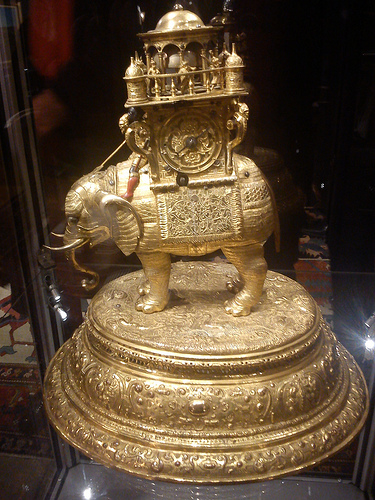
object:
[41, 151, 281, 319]
elephant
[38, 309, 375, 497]
table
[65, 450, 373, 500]
surface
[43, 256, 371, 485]
bottom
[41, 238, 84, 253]
tusk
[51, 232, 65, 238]
tusk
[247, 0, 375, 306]
surface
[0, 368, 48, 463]
mat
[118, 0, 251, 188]
model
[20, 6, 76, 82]
object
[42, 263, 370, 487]
statue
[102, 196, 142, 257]
ear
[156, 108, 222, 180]
clock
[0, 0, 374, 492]
case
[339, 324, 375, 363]
spotlight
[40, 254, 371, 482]
dome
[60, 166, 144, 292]
head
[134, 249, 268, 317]
feet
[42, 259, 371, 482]
base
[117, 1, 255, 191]
decoration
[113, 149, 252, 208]
back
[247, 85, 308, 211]
reflection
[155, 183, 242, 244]
blanket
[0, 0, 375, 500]
museum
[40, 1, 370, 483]
statue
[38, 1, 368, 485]
gold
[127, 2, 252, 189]
building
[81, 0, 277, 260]
details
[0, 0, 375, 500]
windows